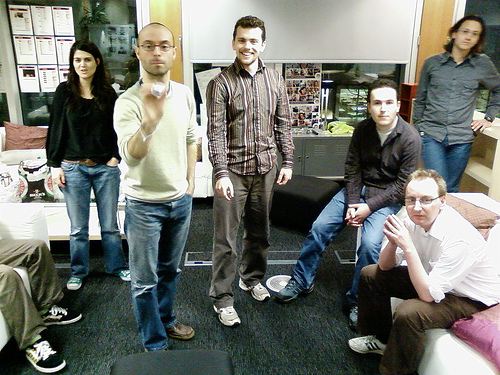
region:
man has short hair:
[122, 14, 165, 69]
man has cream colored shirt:
[118, 91, 200, 181]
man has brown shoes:
[154, 311, 195, 358]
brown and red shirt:
[211, 54, 308, 202]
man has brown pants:
[190, 157, 283, 322]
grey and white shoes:
[211, 277, 277, 337]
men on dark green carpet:
[177, 284, 309, 373]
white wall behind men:
[165, 13, 425, 82]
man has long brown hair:
[431, 18, 493, 58]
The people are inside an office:
[1, 15, 492, 360]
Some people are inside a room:
[20, 1, 476, 356]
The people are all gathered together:
[13, 23, 480, 349]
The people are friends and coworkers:
[7, 21, 488, 361]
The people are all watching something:
[7, 15, 490, 361]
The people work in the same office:
[16, 23, 491, 368]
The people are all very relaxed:
[7, 23, 492, 344]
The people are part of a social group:
[17, 27, 488, 347]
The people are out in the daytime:
[10, 27, 480, 357]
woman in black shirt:
[41, 38, 143, 292]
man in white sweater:
[112, 17, 205, 351]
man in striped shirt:
[203, 12, 301, 334]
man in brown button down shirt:
[277, 74, 429, 324]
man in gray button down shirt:
[407, 12, 494, 202]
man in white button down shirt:
[345, 163, 497, 369]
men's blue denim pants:
[118, 189, 199, 355]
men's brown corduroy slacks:
[207, 160, 279, 308]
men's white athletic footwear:
[205, 276, 272, 333]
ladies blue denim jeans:
[54, 153, 135, 283]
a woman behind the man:
[46, 37, 137, 302]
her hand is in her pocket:
[93, 146, 128, 181]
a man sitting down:
[274, 69, 416, 324]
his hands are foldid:
[371, 216, 412, 259]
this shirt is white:
[389, 194, 497, 300]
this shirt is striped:
[206, 55, 296, 172]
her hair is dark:
[63, 42, 113, 106]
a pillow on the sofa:
[13, 160, 63, 205]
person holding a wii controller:
[136, 85, 181, 149]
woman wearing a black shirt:
[39, 75, 133, 187]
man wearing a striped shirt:
[192, 51, 307, 213]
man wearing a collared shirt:
[359, 113, 417, 161]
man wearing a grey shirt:
[410, 43, 497, 150]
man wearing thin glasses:
[135, 35, 182, 63]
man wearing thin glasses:
[407, 181, 444, 216]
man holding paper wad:
[146, 79, 168, 104]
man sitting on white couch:
[340, 164, 498, 374]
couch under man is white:
[357, 184, 499, 373]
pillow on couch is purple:
[449, 292, 499, 368]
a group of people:
[9, 5, 494, 367]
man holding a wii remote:
[95, 18, 220, 353]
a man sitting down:
[349, 168, 496, 374]